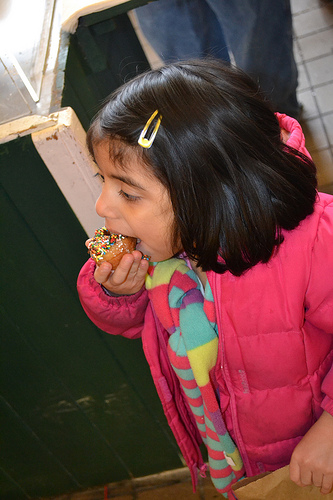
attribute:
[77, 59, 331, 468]
girl — young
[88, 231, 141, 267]
donut — meal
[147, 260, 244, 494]
scarf — colorful, winter, striped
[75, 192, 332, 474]
coat — pink, cold-weather, puffy, winter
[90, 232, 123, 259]
sprinkles — multicolored, colored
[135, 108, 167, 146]
barette — gold, yellow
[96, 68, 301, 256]
hair — shiny, brown, shoulder length, black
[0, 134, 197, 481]
wall — green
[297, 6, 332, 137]
floor — white, tile, black, tiled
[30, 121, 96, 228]
trim — white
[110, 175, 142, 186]
eyebrows — full, thick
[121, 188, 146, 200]
eyes — brown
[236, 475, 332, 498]
bag — brown, paper